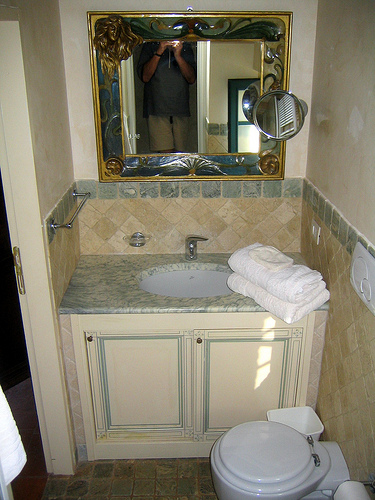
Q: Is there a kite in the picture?
A: No, there are no kites.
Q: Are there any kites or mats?
A: No, there are no kites or mats.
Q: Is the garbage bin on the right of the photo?
A: Yes, the garbage bin is on the right of the image.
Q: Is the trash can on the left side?
A: No, the trash can is on the right of the image.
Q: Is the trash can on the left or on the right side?
A: The trash can is on the right of the image.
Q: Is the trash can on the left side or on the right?
A: The trash can is on the right of the image.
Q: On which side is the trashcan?
A: The trashcan is on the right of the image.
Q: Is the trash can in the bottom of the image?
A: Yes, the trash can is in the bottom of the image.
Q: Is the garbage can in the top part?
A: No, the garbage can is in the bottom of the image.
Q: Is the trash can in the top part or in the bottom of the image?
A: The trash can is in the bottom of the image.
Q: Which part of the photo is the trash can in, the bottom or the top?
A: The trash can is in the bottom of the image.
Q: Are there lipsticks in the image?
A: No, there are no lipsticks.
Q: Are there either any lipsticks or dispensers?
A: No, there are no lipsticks or dispensers.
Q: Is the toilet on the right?
A: Yes, the toilet is on the right of the image.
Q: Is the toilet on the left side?
A: No, the toilet is on the right of the image.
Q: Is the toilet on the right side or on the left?
A: The toilet is on the right of the image.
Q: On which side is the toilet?
A: The toilet is on the right of the image.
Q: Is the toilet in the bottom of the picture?
A: Yes, the toilet is in the bottom of the image.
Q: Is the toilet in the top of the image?
A: No, the toilet is in the bottom of the image.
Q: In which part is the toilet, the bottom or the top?
A: The toilet is in the bottom of the image.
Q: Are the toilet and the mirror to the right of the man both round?
A: Yes, both the toilet and the mirror are round.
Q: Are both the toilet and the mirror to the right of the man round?
A: Yes, both the toilet and the mirror are round.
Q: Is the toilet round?
A: Yes, the toilet is round.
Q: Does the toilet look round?
A: Yes, the toilet is round.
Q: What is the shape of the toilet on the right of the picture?
A: The toilet is round.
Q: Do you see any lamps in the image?
A: No, there are no lamps.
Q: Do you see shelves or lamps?
A: No, there are no lamps or shelves.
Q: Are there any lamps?
A: No, there are no lamps.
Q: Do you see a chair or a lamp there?
A: No, there are no lamps or chairs.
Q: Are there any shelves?
A: No, there are no shelves.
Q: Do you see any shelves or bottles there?
A: No, there are no shelves or bottles.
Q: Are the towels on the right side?
A: Yes, the towels are on the right of the image.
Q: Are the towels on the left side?
A: No, the towels are on the right of the image.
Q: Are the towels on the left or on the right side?
A: The towels are on the right of the image.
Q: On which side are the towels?
A: The towels are on the right of the image.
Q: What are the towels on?
A: The towels are on the counter.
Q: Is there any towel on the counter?
A: Yes, there are towels on the counter.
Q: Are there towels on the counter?
A: Yes, there are towels on the counter.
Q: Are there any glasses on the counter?
A: No, there are towels on the counter.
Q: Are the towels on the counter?
A: Yes, the towels are on the counter.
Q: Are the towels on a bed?
A: No, the towels are on the counter.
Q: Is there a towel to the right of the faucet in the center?
A: Yes, there are towels to the right of the tap.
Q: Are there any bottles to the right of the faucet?
A: No, there are towels to the right of the faucet.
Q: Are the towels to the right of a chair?
A: No, the towels are to the right of a faucet.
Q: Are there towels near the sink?
A: Yes, there are towels near the sink.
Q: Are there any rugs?
A: No, there are no rugs.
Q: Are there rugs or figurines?
A: No, there are no rugs or figurines.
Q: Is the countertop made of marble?
A: Yes, the countertop is made of marble.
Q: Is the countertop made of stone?
A: No, the countertop is made of marble.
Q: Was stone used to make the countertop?
A: No, the countertop is made of marble.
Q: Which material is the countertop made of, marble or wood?
A: The countertop is made of marble.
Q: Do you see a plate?
A: No, there are no plates.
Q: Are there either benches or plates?
A: No, there are no plates or benches.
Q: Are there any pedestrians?
A: No, there are no pedestrians.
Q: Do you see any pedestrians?
A: No, there are no pedestrians.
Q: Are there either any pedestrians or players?
A: No, there are no pedestrians or players.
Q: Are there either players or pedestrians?
A: No, there are no pedestrians or players.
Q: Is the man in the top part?
A: Yes, the man is in the top of the image.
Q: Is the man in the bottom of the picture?
A: No, the man is in the top of the image.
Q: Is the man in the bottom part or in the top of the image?
A: The man is in the top of the image.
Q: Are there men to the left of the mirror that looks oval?
A: Yes, there is a man to the left of the mirror.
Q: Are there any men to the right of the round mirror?
A: No, the man is to the left of the mirror.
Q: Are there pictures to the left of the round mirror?
A: No, there is a man to the left of the mirror.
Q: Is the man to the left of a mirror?
A: Yes, the man is to the left of a mirror.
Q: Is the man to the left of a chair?
A: No, the man is to the left of a mirror.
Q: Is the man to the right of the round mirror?
A: No, the man is to the left of the mirror.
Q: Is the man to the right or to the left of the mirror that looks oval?
A: The man is to the left of the mirror.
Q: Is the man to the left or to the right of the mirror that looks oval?
A: The man is to the left of the mirror.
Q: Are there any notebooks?
A: No, there are no notebooks.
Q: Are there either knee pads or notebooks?
A: No, there are no notebooks or knee pads.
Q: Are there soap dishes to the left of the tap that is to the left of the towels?
A: Yes, there is a soap dish to the left of the tap.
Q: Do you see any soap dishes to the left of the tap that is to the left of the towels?
A: Yes, there is a soap dish to the left of the tap.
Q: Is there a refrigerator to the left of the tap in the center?
A: No, there is a soap dish to the left of the tap.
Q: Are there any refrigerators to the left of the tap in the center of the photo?
A: No, there is a soap dish to the left of the tap.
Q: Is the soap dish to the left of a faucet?
A: Yes, the soap dish is to the left of a faucet.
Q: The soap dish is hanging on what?
A: The soap dish is hanging on the wall.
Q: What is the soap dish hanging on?
A: The soap dish is hanging on the wall.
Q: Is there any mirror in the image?
A: Yes, there is a mirror.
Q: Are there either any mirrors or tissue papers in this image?
A: Yes, there is a mirror.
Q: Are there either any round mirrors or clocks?
A: Yes, there is a round mirror.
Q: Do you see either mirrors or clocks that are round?
A: Yes, the mirror is round.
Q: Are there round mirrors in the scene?
A: Yes, there is a round mirror.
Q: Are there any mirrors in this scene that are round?
A: Yes, there is a mirror that is round.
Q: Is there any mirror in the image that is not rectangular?
A: Yes, there is a round mirror.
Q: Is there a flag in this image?
A: No, there are no flags.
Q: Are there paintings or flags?
A: No, there are no flags or paintings.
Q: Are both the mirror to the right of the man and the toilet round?
A: Yes, both the mirror and the toilet are round.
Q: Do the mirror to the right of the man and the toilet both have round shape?
A: Yes, both the mirror and the toilet are round.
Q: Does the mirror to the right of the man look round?
A: Yes, the mirror is round.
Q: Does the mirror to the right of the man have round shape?
A: Yes, the mirror is round.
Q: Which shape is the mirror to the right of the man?
A: The mirror is round.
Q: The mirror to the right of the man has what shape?
A: The mirror is round.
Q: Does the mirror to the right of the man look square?
A: No, the mirror is round.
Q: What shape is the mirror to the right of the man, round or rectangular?
A: The mirror is round.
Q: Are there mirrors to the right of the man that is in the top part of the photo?
A: Yes, there is a mirror to the right of the man.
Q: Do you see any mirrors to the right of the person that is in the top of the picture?
A: Yes, there is a mirror to the right of the man.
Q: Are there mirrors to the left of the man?
A: No, the mirror is to the right of the man.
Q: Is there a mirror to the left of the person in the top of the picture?
A: No, the mirror is to the right of the man.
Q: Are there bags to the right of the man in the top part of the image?
A: No, there is a mirror to the right of the man.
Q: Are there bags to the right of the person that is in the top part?
A: No, there is a mirror to the right of the man.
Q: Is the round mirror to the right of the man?
A: Yes, the mirror is to the right of the man.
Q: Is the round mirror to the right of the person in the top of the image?
A: Yes, the mirror is to the right of the man.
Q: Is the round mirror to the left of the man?
A: No, the mirror is to the right of the man.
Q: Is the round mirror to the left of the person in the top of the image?
A: No, the mirror is to the right of the man.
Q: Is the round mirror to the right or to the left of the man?
A: The mirror is to the right of the man.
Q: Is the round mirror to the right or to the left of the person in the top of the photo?
A: The mirror is to the right of the man.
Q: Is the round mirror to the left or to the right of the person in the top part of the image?
A: The mirror is to the right of the man.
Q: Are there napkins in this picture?
A: No, there are no napkins.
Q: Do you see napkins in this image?
A: No, there are no napkins.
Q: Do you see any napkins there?
A: No, there are no napkins.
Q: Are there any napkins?
A: No, there are no napkins.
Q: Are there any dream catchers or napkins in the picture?
A: No, there are no napkins or dream catchers.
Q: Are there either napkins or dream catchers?
A: No, there are no napkins or dream catchers.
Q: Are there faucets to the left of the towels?
A: Yes, there is a faucet to the left of the towels.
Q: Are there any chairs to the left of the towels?
A: No, there is a faucet to the left of the towels.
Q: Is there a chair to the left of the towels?
A: No, there is a faucet to the left of the towels.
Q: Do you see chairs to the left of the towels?
A: No, there is a faucet to the left of the towels.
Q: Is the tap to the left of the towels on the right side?
A: Yes, the tap is to the left of the towels.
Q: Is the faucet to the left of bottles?
A: No, the faucet is to the left of the towels.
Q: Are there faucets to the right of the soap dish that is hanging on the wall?
A: Yes, there is a faucet to the right of the soap dish.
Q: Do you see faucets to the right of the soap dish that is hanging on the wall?
A: Yes, there is a faucet to the right of the soap dish.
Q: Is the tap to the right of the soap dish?
A: Yes, the tap is to the right of the soap dish.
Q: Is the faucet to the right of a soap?
A: No, the faucet is to the right of the soap dish.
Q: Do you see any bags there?
A: No, there are no bags.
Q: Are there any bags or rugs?
A: No, there are no bags or rugs.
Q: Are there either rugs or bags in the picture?
A: No, there are no bags or rugs.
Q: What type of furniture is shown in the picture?
A: The furniture is drawers.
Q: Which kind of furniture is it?
A: The pieces of furniture are drawers.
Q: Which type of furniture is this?
A: These are drawers.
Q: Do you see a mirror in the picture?
A: Yes, there is a mirror.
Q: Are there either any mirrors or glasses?
A: Yes, there is a mirror.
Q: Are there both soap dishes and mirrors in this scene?
A: Yes, there are both a mirror and a soap dish.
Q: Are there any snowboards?
A: No, there are no snowboards.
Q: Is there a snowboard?
A: No, there are no snowboards.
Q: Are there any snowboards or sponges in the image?
A: No, there are no snowboards or sponges.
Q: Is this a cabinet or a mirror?
A: This is a mirror.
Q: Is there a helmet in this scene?
A: No, there are no helmets.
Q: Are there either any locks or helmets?
A: No, there are no helmets or locks.